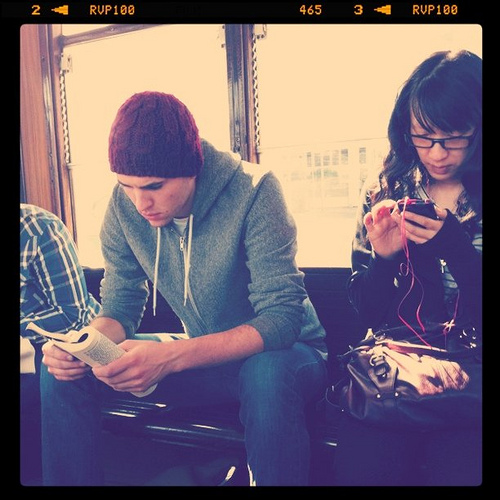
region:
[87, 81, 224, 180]
a knit hat on head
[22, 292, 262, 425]
a book in his hands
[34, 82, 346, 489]
a guy reading a book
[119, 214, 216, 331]
two white strings coming from shirt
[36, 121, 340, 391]
a gray hoodie and jeans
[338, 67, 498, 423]
a girl on a phone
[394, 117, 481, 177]
black glasses on her face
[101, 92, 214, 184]
a red hat on his head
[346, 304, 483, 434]
a black purse on her lap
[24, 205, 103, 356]
a blue shirt with white stripes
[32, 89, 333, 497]
Man reading a book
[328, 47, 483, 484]
Woman scrolling on her smartphone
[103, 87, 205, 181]
Burgundy toboggan worn by young man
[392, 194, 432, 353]
Pink earbud cord plugged in smartphone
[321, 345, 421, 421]
Woman's purse beside her on seat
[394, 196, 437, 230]
Smartphone in woman's hands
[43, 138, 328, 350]
Gray hoodie worn by young man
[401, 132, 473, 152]
Eye glasses on woman's face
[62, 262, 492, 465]
Bench passengers are sitting on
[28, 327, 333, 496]
Jeans worn by young man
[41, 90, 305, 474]
man sitting down reading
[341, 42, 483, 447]
woman is using her phone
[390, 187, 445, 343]
pink headphone plugged into phone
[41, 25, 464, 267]
windows behind the people sitting down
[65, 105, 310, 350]
man wearing a grey hooded jacket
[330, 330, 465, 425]
woman's brown purse is in her bag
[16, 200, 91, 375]
person at far left wearing plaid shirt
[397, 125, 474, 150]
woman wearing black glasses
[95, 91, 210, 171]
man wearing burgundy hat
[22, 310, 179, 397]
man has folded the book he is reading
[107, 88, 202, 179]
Wool hat on man's head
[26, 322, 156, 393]
Book in man's hands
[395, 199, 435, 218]
Cell phone in girl's hands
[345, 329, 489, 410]
Leather purse in girl's lap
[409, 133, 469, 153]
Glasses on girl's face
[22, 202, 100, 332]
Plaid shirt on person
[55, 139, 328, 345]
Gray hoodie on man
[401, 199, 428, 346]
Pink wires on phone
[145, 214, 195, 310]
White strings on hooded sweatshirt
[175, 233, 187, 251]
Zipper on front of sweatshirt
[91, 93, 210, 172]
knit hat on person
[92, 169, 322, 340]
shirt on the person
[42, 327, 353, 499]
pants on the person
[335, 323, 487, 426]
purse in woman's lap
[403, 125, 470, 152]
glasses on the person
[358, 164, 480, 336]
shirt on the person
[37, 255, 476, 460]
bench people sit on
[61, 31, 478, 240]
window behind the people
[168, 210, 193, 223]
shirt on the man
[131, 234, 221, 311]
strings on the shirt